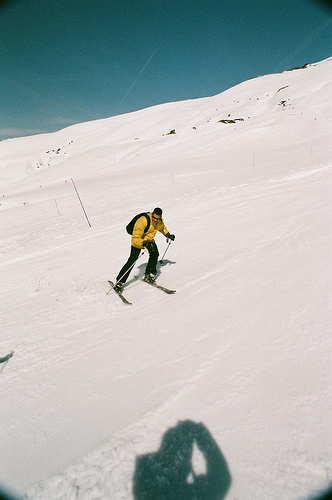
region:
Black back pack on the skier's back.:
[125, 207, 149, 236]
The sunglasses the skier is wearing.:
[148, 213, 159, 219]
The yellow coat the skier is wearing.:
[133, 212, 167, 240]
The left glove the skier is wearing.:
[144, 236, 153, 249]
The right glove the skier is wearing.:
[164, 232, 175, 238]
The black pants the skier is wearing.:
[125, 247, 158, 281]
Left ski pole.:
[108, 240, 149, 294]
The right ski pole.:
[162, 236, 166, 269]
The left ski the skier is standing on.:
[106, 281, 132, 307]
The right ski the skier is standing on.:
[140, 276, 174, 297]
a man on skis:
[105, 205, 177, 305]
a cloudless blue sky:
[1, 0, 331, 142]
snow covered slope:
[0, 58, 329, 498]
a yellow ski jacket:
[127, 212, 168, 248]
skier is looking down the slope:
[107, 205, 178, 304]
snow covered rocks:
[34, 61, 312, 168]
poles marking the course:
[49, 175, 95, 227]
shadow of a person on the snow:
[129, 416, 234, 497]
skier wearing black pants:
[106, 205, 177, 306]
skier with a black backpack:
[105, 206, 179, 305]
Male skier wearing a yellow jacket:
[98, 205, 186, 310]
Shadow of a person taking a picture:
[121, 406, 244, 498]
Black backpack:
[117, 206, 151, 240]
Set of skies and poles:
[102, 243, 192, 305]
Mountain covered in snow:
[3, 59, 316, 186]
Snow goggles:
[148, 213, 167, 224]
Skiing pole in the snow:
[56, 170, 104, 241]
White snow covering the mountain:
[175, 93, 331, 231]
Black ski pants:
[109, 242, 167, 283]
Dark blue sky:
[5, 3, 314, 120]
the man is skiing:
[91, 190, 229, 317]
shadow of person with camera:
[111, 405, 290, 497]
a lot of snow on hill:
[151, 82, 297, 199]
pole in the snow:
[61, 161, 111, 241]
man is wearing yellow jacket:
[102, 198, 201, 295]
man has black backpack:
[115, 207, 196, 314]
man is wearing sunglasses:
[111, 193, 184, 313]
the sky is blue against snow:
[77, 51, 215, 151]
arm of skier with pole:
[1, 323, 17, 383]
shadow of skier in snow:
[110, 247, 201, 299]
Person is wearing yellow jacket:
[131, 217, 184, 259]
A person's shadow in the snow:
[126, 402, 266, 495]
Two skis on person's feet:
[95, 284, 200, 311]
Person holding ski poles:
[92, 269, 157, 308]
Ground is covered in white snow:
[68, 325, 289, 436]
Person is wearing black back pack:
[124, 190, 155, 254]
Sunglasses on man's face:
[150, 211, 181, 235]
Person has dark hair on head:
[146, 194, 182, 239]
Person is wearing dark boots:
[107, 278, 130, 302]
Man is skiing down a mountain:
[95, 194, 243, 328]